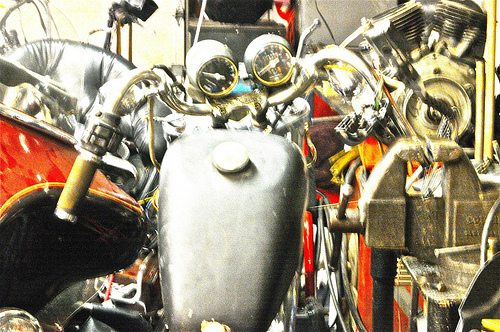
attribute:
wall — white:
[295, 0, 398, 45]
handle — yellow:
[58, 153, 98, 214]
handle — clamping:
[322, 181, 363, 273]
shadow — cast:
[233, 164, 253, 176]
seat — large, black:
[142, 89, 407, 329]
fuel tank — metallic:
[151, 100, 301, 327]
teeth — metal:
[394, 138, 463, 163]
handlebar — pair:
[49, 146, 99, 222]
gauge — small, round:
[184, 49, 262, 108]